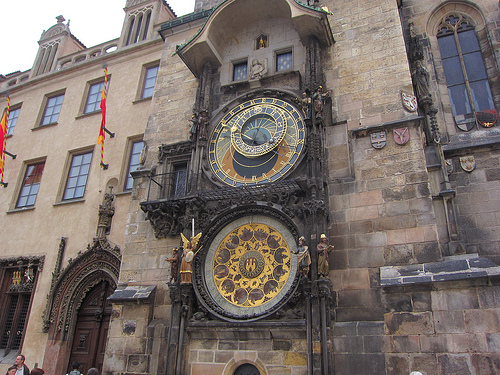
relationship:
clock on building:
[197, 101, 309, 316] [2, 0, 497, 374]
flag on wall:
[89, 57, 124, 176] [15, 35, 146, 373]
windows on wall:
[2, 56, 159, 215] [0, 36, 163, 374]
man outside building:
[6, 352, 35, 374] [24, 57, 497, 364]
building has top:
[46, 26, 446, 259] [20, 10, 235, 65]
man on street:
[6, 352, 35, 374] [4, 349, 495, 373]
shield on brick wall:
[365, 131, 393, 156] [99, 0, 499, 374]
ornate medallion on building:
[210, 222, 294, 309] [102, 1, 494, 373]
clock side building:
[197, 96, 306, 193] [6, 0, 496, 332]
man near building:
[6, 352, 35, 374] [2, 0, 497, 374]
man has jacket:
[4, 333, 44, 372] [12, 367, 37, 373]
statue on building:
[242, 55, 272, 83] [130, 5, 484, 374]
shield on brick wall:
[167, 200, 335, 327] [338, 125, 416, 263]